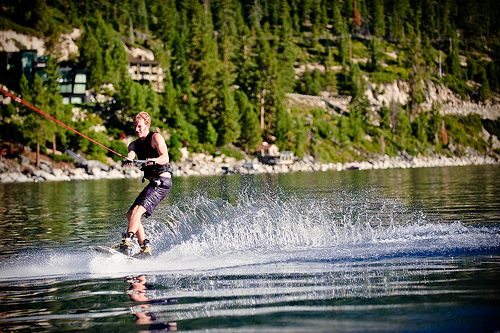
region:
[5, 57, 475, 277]
The man is enjoying waterskiing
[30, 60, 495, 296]
The man is being pulled by a rope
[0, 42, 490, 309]
The man is moving fast through the water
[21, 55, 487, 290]
The man is on a water ski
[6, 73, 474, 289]
The man is water skiing on a lake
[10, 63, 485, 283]
A man is skiing on a river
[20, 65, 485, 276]
A man is getting some recreation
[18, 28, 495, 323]
A man is having some fun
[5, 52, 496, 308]
A man is enjoying the sunshine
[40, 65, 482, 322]
A man is enjoying his day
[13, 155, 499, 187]
rocky shore by water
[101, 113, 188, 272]
man water skiing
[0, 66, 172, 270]
man holding orange line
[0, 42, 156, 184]
building by shore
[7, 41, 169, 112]
wooden deck on house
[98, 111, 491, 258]
skiing man leaving waves in wake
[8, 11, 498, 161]
pine trees on hill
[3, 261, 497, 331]
ripples on water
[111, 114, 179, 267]
man wearing shorts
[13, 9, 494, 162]
forest of pine trees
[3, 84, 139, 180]
a red tether cord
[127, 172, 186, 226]
mens swim trunks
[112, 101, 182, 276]
a man water skiing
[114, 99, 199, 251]
a man wearing swim trunks and safety vest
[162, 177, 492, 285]
the wake behind a water skiier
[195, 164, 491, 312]
a large body of water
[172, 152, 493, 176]
a rocky shore line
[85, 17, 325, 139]
trees along the shore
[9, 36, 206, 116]
houses that are blocked by trees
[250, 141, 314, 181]
a small house right on the water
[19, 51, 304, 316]
a man water skiing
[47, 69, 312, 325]
a man on water skies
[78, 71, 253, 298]
a man wearing a life vest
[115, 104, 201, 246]
a man holding onto the rope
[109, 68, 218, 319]
a man skiing on the water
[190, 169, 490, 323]
a body of water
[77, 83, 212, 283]
a man wearing swim trunks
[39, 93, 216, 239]
a man holding onto a rope bar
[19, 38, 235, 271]
a man holding onto a red rope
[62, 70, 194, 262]
a man is water skiing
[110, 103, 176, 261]
a surfer in the water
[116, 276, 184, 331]
reflection of person in the water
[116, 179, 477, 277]
splashes of water behind a surfer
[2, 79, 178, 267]
surfer holding a red rope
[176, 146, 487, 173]
stones on the shore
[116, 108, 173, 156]
person is blonde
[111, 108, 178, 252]
surfer wears black cloths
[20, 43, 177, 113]
buildings on side the river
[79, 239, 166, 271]
surfboard is white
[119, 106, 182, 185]
surfer wears a black top